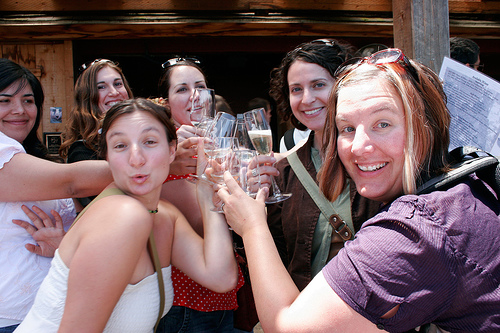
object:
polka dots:
[200, 294, 203, 296]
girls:
[217, 49, 500, 333]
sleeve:
[320, 194, 452, 332]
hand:
[216, 171, 270, 236]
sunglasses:
[162, 58, 200, 69]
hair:
[267, 39, 357, 131]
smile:
[354, 161, 391, 179]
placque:
[42, 131, 65, 158]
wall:
[0, 48, 73, 152]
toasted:
[190, 88, 294, 215]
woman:
[161, 58, 272, 333]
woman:
[11, 98, 239, 333]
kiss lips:
[129, 174, 149, 179]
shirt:
[160, 124, 245, 313]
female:
[0, 61, 111, 333]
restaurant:
[0, 0, 499, 165]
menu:
[438, 56, 500, 172]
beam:
[392, 0, 449, 76]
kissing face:
[106, 112, 170, 196]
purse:
[150, 231, 166, 332]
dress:
[160, 125, 245, 312]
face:
[336, 80, 404, 197]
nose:
[350, 134, 375, 157]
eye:
[341, 126, 356, 133]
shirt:
[323, 172, 500, 333]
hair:
[57, 59, 134, 159]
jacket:
[266, 129, 386, 303]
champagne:
[248, 130, 273, 154]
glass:
[244, 108, 294, 204]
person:
[257, 39, 398, 290]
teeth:
[309, 111, 311, 114]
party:
[0, 39, 500, 333]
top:
[15, 248, 176, 333]